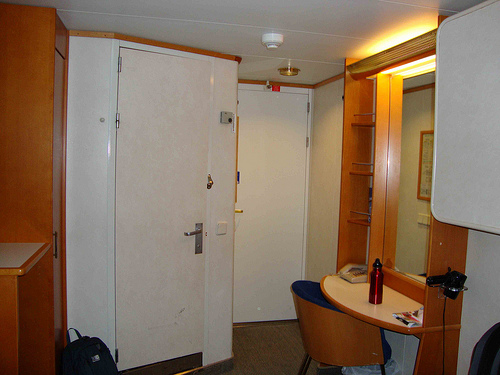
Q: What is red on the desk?
A: Water bottle.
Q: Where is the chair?
A: Under the desk.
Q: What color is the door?
A: White.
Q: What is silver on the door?
A: The door.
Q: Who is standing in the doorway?
A: Nobody.